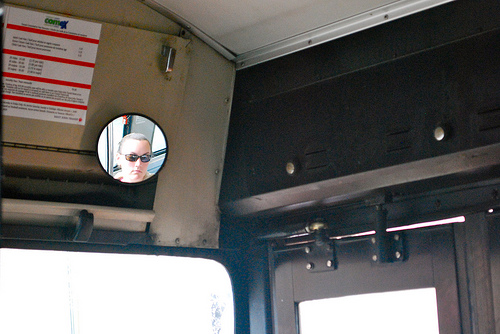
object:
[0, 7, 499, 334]
bus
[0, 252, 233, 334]
window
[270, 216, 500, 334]
door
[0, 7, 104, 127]
card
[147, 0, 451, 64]
ceiling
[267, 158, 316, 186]
cabinet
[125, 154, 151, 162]
sunglasses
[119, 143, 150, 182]
face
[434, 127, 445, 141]
screws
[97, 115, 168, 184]
reflection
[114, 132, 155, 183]
passenger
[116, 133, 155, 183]
woman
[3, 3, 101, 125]
letter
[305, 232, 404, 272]
bolts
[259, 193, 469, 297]
objects